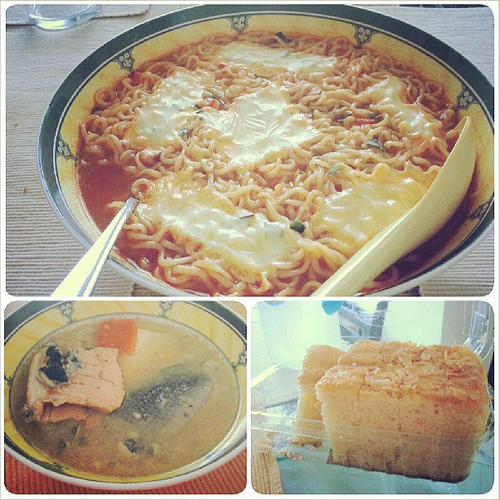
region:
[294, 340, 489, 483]
pound cake on tray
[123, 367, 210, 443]
grey fish head in bowl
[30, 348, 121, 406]
white fish in bowl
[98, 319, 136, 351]
carrot slice in bowl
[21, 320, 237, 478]
fish soup in bowl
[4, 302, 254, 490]
green and yellow bowl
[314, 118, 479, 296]
ivory plastic soup spoon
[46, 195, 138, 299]
silver metal spoon in bowl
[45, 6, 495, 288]
noodle soup in bowl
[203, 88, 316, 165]
melted cheese on soup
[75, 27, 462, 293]
some soup in a bowl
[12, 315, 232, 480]
some soup in a bowl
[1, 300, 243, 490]
A black and yellow bowl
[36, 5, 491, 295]
A black and yellow bowl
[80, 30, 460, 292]
some noodles in a bowl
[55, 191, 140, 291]
A silver utensil handle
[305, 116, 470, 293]
A white soup spoon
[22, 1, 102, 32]
A drinking glass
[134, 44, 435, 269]
some melted cheese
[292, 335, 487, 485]
A small pastry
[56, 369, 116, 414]
meat in the bowl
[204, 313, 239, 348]
a bowl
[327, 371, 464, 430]
a cake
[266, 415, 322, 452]
a clear container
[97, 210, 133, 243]
a utensil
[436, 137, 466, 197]
a spoon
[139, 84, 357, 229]
noodles and cheese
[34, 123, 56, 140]
rim of the bowl is green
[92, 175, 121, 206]
the sauce is red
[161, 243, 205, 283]
noodles in the bowl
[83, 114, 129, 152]
White noodles in a bowl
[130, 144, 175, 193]
White noodles in a bowl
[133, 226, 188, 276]
White noodles in a bowl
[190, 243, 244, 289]
White noodles in a bowl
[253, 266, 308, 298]
White noodles in a bowl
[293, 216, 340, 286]
White noodles in a bowl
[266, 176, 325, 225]
White noodles in a bowl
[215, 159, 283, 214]
White noodles in a bowl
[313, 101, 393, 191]
White noodles in a bowl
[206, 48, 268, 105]
White noodles in a bowl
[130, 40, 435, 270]
some melted cheese on some noodles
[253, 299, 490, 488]
A small plastic container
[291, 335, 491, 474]
A small pastry in a container